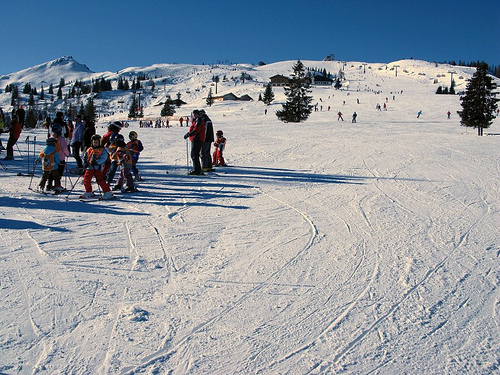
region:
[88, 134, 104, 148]
the head of the child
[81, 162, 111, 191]
a pair of red pants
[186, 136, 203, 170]
a pair of black pants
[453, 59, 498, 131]
a green tree on the snow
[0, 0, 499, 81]
a clear blue sky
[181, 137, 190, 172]
a ski pole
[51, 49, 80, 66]
the peak of a mountain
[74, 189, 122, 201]
ski boots on the child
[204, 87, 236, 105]
a house in the distance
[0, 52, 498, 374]
white snow on the ground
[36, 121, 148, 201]
these are children in the photo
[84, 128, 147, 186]
the children are in a line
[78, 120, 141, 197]
the children are snow skating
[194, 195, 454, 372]
the place is full of snow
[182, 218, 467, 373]
lines are on the ground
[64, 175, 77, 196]
this is a stick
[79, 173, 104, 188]
the legs are apart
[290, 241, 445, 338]
the snow is white in color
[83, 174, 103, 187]
the trousers is red in color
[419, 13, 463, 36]
the sky is blue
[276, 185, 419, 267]
Ground is white color.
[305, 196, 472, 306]
Ground is covered with snow.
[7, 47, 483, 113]
Foot hill is covered with snow.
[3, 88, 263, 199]
People are standing in snow.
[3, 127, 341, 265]
Shadow falls on ground.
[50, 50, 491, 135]
Pine tree is behind the people.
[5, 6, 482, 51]
Sky is blue color.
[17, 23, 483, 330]
Day time picture.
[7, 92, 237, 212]
People are holding ski poles in hand.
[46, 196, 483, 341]
Markings are seen in snow.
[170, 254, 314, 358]
The snow is white.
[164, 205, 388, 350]
The snow is white.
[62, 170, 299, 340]
The snow is white.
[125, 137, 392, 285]
The snow is white.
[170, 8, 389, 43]
this is the sky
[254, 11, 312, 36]
the sky is blue in color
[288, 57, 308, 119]
this is a tree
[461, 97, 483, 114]
the tree has green leaves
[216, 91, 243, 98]
this is a building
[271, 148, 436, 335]
this is a snow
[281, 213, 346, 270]
the snow is white in appearance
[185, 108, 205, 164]
this is a man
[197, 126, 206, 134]
this is a jacket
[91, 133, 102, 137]
this is a helmet